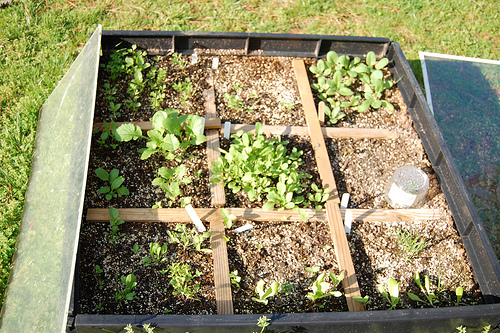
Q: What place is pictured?
A: It is a farm.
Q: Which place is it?
A: It is a farm.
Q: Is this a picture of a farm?
A: Yes, it is showing a farm.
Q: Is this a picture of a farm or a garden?
A: It is showing a farm.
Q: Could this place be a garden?
A: No, it is a farm.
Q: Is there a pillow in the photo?
A: No, there are no pillows.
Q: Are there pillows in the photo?
A: No, there are no pillows.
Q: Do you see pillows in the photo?
A: No, there are no pillows.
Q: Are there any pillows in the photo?
A: No, there are no pillows.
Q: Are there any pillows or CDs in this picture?
A: No, there are no pillows or cds.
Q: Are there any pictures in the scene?
A: No, there are no pictures.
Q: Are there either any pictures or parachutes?
A: No, there are no pictures or parachutes.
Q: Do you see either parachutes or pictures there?
A: No, there are no pictures or parachutes.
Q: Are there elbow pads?
A: No, there are no elbow pads.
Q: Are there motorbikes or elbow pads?
A: No, there are no elbow pads or motorbikes.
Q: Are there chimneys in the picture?
A: No, there are no chimneys.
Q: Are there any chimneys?
A: No, there are no chimneys.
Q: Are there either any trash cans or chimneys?
A: No, there are no chimneys or trash cans.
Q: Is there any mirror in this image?
A: No, there are no mirrors.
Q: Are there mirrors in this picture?
A: No, there are no mirrors.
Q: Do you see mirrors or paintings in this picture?
A: No, there are no mirrors or paintings.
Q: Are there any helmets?
A: No, there are no helmets.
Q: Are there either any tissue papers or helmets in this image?
A: No, there are no helmets or tissue papers.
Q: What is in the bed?
A: The plant is in the bed.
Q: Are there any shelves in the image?
A: No, there are no shelves.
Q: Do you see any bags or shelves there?
A: No, there are no shelves or bags.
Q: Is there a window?
A: Yes, there is a window.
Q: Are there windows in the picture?
A: Yes, there is a window.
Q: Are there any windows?
A: Yes, there is a window.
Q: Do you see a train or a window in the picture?
A: Yes, there is a window.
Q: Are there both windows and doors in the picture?
A: No, there is a window but no doors.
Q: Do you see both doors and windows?
A: No, there is a window but no doors.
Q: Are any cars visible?
A: No, there are no cars.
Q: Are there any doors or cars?
A: No, there are no cars or doors.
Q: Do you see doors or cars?
A: No, there are no cars or doors.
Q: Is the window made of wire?
A: Yes, the window is made of wire.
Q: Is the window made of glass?
A: No, the window is made of wire.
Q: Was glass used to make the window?
A: No, the window is made of wire.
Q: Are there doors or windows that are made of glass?
A: No, there is a window but it is made of wire.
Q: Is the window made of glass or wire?
A: The window is made of wire.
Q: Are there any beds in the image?
A: Yes, there is a bed.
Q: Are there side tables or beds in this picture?
A: Yes, there is a bed.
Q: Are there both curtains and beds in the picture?
A: No, there is a bed but no curtains.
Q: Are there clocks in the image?
A: No, there are no clocks.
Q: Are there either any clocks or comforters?
A: No, there are no clocks or comforters.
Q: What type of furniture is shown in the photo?
A: The furniture is a bed.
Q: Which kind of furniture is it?
A: The piece of furniture is a bed.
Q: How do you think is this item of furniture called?
A: This is a bed.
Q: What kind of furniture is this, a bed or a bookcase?
A: This is a bed.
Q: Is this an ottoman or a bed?
A: This is a bed.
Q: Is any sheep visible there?
A: No, there is no sheep.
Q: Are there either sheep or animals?
A: No, there are no sheep or animals.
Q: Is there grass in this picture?
A: Yes, there is grass.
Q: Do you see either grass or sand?
A: Yes, there is grass.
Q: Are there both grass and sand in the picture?
A: No, there is grass but no sand.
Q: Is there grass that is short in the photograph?
A: Yes, there is short grass.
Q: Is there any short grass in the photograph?
A: Yes, there is short grass.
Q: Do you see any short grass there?
A: Yes, there is short grass.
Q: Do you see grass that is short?
A: Yes, there is grass that is short.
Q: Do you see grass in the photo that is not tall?
A: Yes, there is short grass.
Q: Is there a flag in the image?
A: No, there are no flags.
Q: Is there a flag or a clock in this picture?
A: No, there are no flags or clocks.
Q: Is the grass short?
A: Yes, the grass is short.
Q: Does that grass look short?
A: Yes, the grass is short.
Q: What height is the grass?
A: The grass is short.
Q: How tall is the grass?
A: The grass is short.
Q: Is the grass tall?
A: No, the grass is short.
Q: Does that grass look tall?
A: No, the grass is short.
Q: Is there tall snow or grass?
A: No, there is grass but it is short.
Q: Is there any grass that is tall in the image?
A: No, there is grass but it is short.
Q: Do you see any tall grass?
A: No, there is grass but it is short.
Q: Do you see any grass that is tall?
A: No, there is grass but it is short.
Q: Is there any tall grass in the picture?
A: No, there is grass but it is short.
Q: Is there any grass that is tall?
A: No, there is grass but it is short.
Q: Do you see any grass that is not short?
A: No, there is grass but it is short.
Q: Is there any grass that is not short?
A: No, there is grass but it is short.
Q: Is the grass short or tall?
A: The grass is short.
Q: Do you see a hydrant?
A: No, there are no fire hydrants.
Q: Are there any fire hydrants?
A: No, there are no fire hydrants.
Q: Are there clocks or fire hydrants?
A: No, there are no fire hydrants or clocks.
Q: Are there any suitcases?
A: No, there are no suitcases.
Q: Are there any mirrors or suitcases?
A: No, there are no suitcases or mirrors.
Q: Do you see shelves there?
A: No, there are no shelves.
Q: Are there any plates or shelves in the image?
A: No, there are no shelves or plates.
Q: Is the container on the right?
A: Yes, the container is on the right of the image.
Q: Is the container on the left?
A: No, the container is on the right of the image.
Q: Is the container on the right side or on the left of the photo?
A: The container is on the right of the image.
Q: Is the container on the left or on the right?
A: The container is on the right of the image.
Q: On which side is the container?
A: The container is on the right of the image.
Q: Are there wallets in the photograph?
A: No, there are no wallets.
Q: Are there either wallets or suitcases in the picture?
A: No, there are no wallets or suitcases.